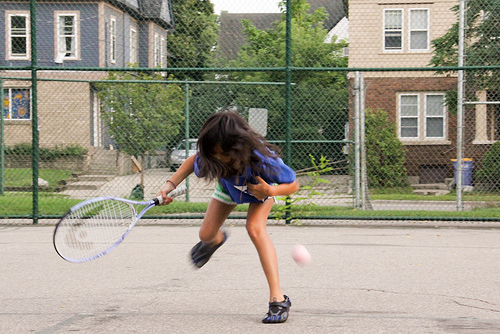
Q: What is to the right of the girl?
A: Ball.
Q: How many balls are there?
A: One.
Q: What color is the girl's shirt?
A: Blue.